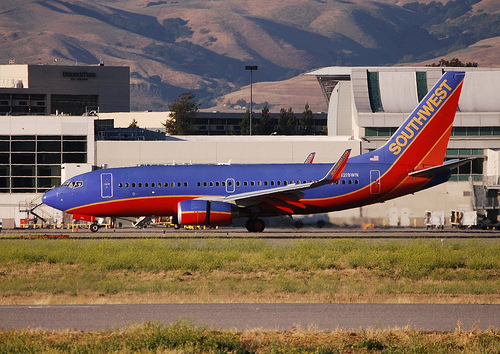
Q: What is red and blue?
A: Plane.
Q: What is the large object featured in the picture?
A: Plane.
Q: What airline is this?
A: Southwest.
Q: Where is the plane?
A: Airport.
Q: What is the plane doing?
A: Sitting.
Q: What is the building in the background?
A: Airport.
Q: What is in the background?
A: Mountain.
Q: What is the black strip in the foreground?
A: Runway.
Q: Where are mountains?
A: In the distance.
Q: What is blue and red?
A: Airplane.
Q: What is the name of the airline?
A: Southwest.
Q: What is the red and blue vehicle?
A: Plane.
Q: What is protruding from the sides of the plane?
A: Wings.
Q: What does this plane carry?
A: Passengers.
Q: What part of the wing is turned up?
A: Tip.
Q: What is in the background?
A: Mountains.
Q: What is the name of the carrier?
A: Southwest airlines.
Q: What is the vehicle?
A: An airplane.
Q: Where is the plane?
A: At the terminal.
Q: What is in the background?
A: Mountains.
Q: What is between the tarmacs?
A: Grass.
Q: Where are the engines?
A: On the wings.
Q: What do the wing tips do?
A: Angle upwards.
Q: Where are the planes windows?
A: On the sides.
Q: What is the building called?
A: The terminal.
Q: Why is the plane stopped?
A: To load passengers.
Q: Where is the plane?
A: At the airport.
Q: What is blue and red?
A: The plane.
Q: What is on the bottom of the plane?
A: Wheels.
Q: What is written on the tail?
A: Southwest.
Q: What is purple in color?
A: Most of the plane.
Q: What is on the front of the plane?
A: Nose.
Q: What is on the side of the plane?
A: Windows.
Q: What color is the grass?
A: Green.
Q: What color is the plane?
A: Blue and red.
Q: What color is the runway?
A: Gray.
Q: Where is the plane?
A: On the runway.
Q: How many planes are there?
A: One.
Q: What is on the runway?
A: A plane.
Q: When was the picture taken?
A: Daytime.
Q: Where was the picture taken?
A: At the airport.